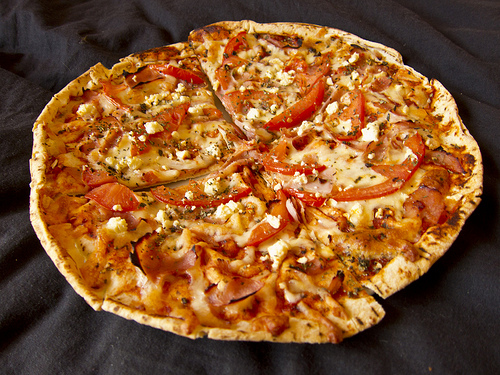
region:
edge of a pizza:
[182, 167, 214, 175]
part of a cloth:
[424, 285, 455, 322]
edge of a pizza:
[242, 332, 277, 354]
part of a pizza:
[245, 262, 296, 322]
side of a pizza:
[249, 297, 294, 352]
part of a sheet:
[260, 357, 279, 364]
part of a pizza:
[203, 252, 243, 313]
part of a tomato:
[81, 176, 100, 196]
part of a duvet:
[381, 327, 412, 367]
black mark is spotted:
[332, 264, 342, 282]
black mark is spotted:
[337, 262, 347, 274]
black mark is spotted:
[336, 273, 344, 278]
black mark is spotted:
[333, 268, 347, 288]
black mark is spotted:
[329, 258, 343, 285]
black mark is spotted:
[336, 267, 343, 291]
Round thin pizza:
[21, 22, 489, 333]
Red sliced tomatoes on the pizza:
[87, 50, 403, 296]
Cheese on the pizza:
[71, 47, 406, 296]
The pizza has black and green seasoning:
[50, 43, 398, 258]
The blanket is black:
[21, 21, 197, 97]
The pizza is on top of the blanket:
[39, 28, 464, 333]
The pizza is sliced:
[37, 27, 427, 311]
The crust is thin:
[31, 199, 201, 354]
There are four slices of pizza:
[50, 46, 428, 301]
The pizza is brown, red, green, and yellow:
[30, 30, 440, 312]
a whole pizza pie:
[21, 18, 479, 344]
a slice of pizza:
[102, 35, 247, 155]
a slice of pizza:
[32, 60, 222, 160]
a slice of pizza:
[20, 167, 235, 307]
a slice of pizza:
[95, 180, 272, 330]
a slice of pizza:
[212, 176, 372, 346]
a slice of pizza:
[280, 175, 460, 291]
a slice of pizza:
[270, 51, 485, 177]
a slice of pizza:
[190, 15, 390, 146]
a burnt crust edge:
[121, 48, 183, 63]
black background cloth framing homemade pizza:
[0, 0, 498, 374]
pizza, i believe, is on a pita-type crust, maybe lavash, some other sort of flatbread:
[23, 18, 485, 348]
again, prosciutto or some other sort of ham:
[92, 168, 284, 264]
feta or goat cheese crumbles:
[114, 78, 387, 248]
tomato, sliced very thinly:
[150, 181, 255, 216]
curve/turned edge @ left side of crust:
[20, 57, 105, 310]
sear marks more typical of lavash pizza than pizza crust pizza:
[350, 185, 485, 331]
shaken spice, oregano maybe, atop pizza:
[127, 171, 375, 284]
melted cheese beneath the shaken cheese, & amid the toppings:
[291, 131, 426, 241]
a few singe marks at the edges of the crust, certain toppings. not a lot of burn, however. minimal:
[120, 21, 310, 68]